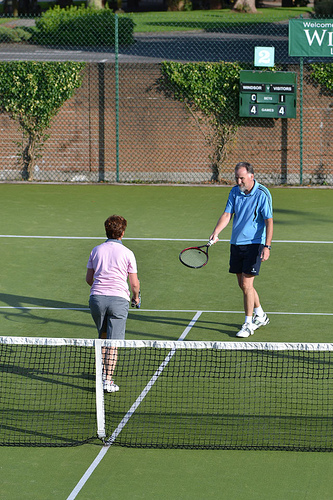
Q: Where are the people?
A: On a tennis court.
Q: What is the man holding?
A: A tennis racket.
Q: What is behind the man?
A: Fence.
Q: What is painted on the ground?
A: White lines.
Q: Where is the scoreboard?
A: On the fence.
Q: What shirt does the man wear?
A: Blue shirt.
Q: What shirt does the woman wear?
A: Pink shirt.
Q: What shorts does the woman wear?
A: Gray shorts.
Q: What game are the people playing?
A: Tennis.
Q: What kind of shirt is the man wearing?
A: A blue polo shirt.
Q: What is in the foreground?
A: A tennis net.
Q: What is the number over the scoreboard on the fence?
A: 2.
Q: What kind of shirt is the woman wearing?
A: A pink short sleeved tee shirt.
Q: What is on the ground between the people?
A: A white line.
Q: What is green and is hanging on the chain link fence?
A: A scoreboard.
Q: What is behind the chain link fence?
A: A brick wall.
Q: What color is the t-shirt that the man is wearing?
A: Blue.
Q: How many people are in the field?
A: 2.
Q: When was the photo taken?
A: Day time.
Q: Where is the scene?
A: At the tennis court.